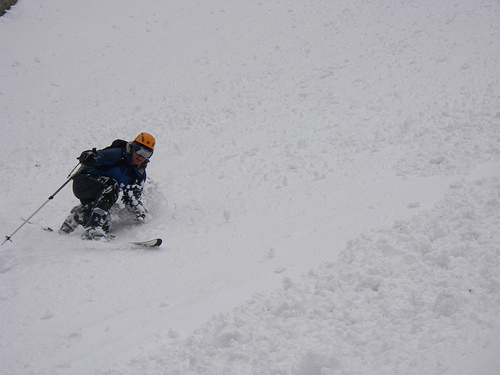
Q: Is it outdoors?
A: Yes, it is outdoors.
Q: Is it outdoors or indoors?
A: It is outdoors.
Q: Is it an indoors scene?
A: No, it is outdoors.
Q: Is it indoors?
A: No, it is outdoors.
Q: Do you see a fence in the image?
A: No, there are no fences.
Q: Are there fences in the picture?
A: No, there are no fences.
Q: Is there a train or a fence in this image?
A: No, there are no fences or trains.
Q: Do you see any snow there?
A: Yes, there is snow.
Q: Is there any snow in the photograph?
A: Yes, there is snow.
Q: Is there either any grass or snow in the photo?
A: Yes, there is snow.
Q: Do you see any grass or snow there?
A: Yes, there is snow.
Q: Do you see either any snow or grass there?
A: Yes, there is snow.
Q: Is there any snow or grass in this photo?
A: Yes, there is snow.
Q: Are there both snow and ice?
A: No, there is snow but no ice.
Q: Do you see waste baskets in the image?
A: No, there are no waste baskets.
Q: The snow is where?
A: The snow is on the ground.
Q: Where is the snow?
A: The snow is on the ground.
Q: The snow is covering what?
A: The snow is covering the mountain.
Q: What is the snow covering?
A: The snow is covering the mountain.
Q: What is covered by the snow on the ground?
A: The mountain is covered by the snow.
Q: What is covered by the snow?
A: The mountain is covered by the snow.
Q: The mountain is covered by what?
A: The mountain is covered by the snow.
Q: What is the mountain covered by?
A: The mountain is covered by the snow.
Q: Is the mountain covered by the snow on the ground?
A: Yes, the mountain is covered by the snow.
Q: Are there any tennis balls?
A: No, there are no tennis balls.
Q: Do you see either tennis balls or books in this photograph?
A: No, there are no tennis balls or books.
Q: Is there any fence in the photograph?
A: No, there are no fences.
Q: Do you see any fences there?
A: No, there are no fences.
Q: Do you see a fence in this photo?
A: No, there are no fences.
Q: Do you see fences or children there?
A: No, there are no fences or children.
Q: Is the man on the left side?
A: Yes, the man is on the left of the image.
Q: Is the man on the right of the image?
A: No, the man is on the left of the image.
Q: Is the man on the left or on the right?
A: The man is on the left of the image.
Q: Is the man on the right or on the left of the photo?
A: The man is on the left of the image.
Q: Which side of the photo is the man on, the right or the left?
A: The man is on the left of the image.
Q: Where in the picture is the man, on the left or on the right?
A: The man is on the left of the image.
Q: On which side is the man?
A: The man is on the left of the image.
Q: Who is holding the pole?
A: The man is holding the pole.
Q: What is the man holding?
A: The man is holding the pole.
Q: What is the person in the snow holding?
A: The man is holding the pole.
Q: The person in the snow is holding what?
A: The man is holding the pole.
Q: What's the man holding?
A: The man is holding the pole.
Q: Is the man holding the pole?
A: Yes, the man is holding the pole.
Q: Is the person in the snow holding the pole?
A: Yes, the man is holding the pole.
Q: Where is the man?
A: The man is in the snow.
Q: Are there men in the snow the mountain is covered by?
A: Yes, there is a man in the snow.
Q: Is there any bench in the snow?
A: No, there is a man in the snow.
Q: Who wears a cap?
A: The man wears a cap.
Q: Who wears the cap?
A: The man wears a cap.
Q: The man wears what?
A: The man wears a cap.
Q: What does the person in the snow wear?
A: The man wears a cap.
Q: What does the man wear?
A: The man wears a cap.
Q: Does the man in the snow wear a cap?
A: Yes, the man wears a cap.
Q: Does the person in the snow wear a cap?
A: Yes, the man wears a cap.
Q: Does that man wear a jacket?
A: No, the man wears a cap.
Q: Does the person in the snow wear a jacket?
A: No, the man wears a cap.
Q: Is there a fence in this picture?
A: No, there are no fences.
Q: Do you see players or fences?
A: No, there are no fences or players.